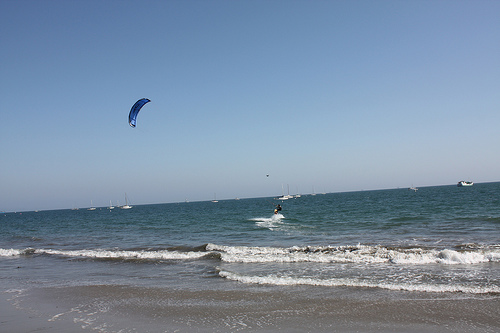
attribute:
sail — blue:
[127, 95, 152, 131]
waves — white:
[1, 243, 500, 294]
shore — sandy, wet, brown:
[4, 280, 499, 332]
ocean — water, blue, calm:
[0, 179, 500, 294]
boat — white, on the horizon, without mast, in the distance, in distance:
[458, 179, 475, 189]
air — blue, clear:
[1, 1, 500, 214]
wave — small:
[248, 211, 288, 233]